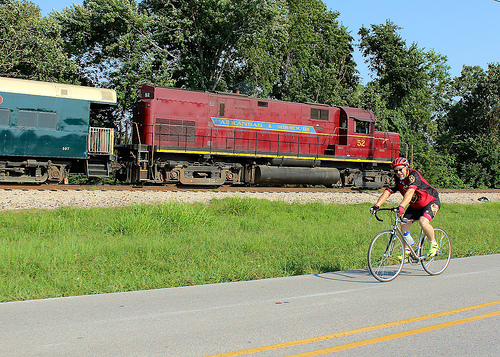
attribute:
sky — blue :
[31, 0, 498, 83]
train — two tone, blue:
[9, 65, 424, 203]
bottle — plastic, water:
[401, 230, 416, 247]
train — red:
[142, 73, 410, 194]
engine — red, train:
[167, 155, 238, 193]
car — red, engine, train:
[2, 66, 133, 196]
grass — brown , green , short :
[18, 211, 118, 258]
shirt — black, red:
[408, 174, 435, 210]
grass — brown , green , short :
[200, 191, 286, 263]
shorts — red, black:
[381, 189, 445, 229]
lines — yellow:
[226, 300, 499, 352]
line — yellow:
[286, 293, 498, 354]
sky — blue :
[348, 7, 490, 82]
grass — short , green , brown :
[3, 200, 493, 289]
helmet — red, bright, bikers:
[390, 155, 409, 167]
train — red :
[120, 79, 440, 214]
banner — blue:
[208, 115, 317, 135]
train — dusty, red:
[124, 74, 426, 209]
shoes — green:
[392, 242, 446, 261]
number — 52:
[355, 136, 368, 150]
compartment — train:
[0, 88, 90, 165]